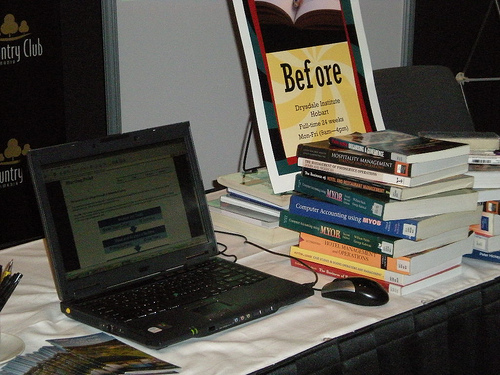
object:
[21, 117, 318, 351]
laptop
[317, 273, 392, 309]
mouse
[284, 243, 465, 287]
book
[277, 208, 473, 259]
book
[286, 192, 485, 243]
book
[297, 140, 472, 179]
book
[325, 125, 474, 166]
book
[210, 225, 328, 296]
wire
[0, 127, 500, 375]
table